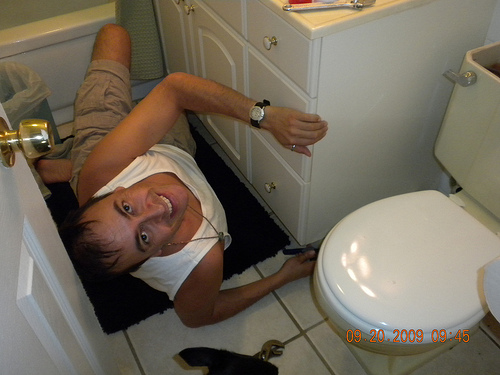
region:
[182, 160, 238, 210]
he is on the floor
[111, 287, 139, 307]
the rug is black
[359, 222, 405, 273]
the lid is down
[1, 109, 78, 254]
the door is open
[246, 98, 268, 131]
he is wearing a watch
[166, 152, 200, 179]
the shirt is white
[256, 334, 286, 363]
the channel locks are on the floor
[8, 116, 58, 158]
the handle is gold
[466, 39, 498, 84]
the lid is off the tank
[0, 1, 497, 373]
Man doing a bathroom repair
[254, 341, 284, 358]
Crescent wrench on floor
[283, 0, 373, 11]
Crescent wrench on bathroom sink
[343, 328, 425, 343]
Photo date stamp of 09.20.2009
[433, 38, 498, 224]
Toilet tank without cover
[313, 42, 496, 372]
White toilet seat and lid on off-white toilet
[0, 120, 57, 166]
Brass door knob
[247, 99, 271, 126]
Watch on man's wrist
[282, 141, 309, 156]
Man's wedding bad moved to thumb during repairs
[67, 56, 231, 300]
Man wearing a white tank top and khaki shorts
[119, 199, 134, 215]
a man's left eye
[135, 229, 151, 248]
a man's right eye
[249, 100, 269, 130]
a man's wrist watch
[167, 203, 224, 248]
a man's gold chain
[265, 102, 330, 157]
a man's left hand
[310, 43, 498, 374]
a white porcelain toilet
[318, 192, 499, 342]
a white plastic toilet seat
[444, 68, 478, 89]
a shiny metal toilet handle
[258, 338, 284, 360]
part of a wrench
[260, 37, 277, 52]
a drawer handle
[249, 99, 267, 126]
The man is wearing a watch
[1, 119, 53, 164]
A knob on the bathroom door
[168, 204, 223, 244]
The man is wearing a necklace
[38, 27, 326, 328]
The man is lying on the bathroom floor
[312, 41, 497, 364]
A toilet next to the man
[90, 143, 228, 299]
The man is wearing a white shirt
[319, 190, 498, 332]
A lid on the toilet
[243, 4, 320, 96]
A drawer beneath the sink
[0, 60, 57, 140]
A trash can by the bathtub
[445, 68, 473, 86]
A silver handle on the toilet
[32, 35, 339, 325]
he is lying on the bathroom floor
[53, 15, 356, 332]
he is doing housework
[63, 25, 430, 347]
he is working on the toilet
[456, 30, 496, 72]
the tank is uncovered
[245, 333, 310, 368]
this is a wrench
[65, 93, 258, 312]
he is wearing a wifebeater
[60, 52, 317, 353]
he is wearing a white tank top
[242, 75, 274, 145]
this is his watch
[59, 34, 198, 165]
a pair of khaki cargo shorts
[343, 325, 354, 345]
orange number on the photo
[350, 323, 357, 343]
orange number on the photo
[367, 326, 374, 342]
orange number on the photo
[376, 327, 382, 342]
orange number on the photo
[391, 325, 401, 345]
orange number on the photo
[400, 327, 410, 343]
orange number on the photo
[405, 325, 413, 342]
orange number on the photo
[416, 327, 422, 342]
orange number on the photo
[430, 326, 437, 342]
orange number on the photo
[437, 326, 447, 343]
orange number on the photo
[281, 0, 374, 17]
wrench on the bathroom counter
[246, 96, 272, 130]
man is wearing a watch